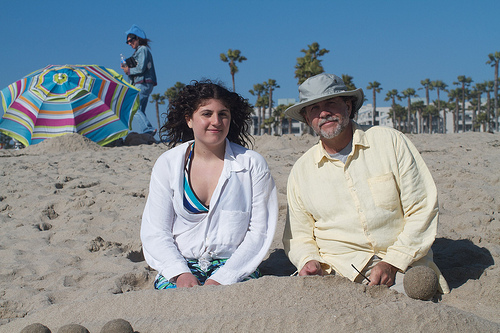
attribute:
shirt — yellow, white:
[282, 117, 442, 282]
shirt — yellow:
[281, 120, 449, 296]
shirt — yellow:
[273, 143, 478, 295]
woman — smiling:
[140, 81, 275, 287]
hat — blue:
[124, 23, 149, 46]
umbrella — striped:
[0, 63, 143, 153]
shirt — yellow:
[285, 124, 440, 289]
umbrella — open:
[1, 65, 139, 146]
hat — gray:
[284, 71, 368, 120]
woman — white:
[133, 78, 291, 289]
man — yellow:
[281, 70, 451, 297]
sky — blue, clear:
[3, 5, 499, 110]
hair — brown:
[166, 75, 256, 142]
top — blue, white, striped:
[177, 148, 216, 219]